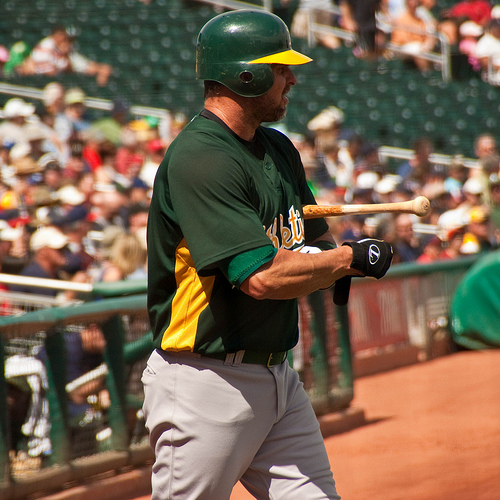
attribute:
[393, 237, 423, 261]
shirt — blue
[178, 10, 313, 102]
green/yellow helmet — green, yellow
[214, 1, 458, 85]
rail — long, gray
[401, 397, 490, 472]
dirt — clay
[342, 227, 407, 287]
glove — black, white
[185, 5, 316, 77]
helmet — green, yellow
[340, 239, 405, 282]
glove — black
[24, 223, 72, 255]
hat — white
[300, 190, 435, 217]
baseball bat — wooden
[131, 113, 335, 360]
shirt — yellow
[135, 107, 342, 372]
shirt — green, yellow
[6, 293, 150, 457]
padding — green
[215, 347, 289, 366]
belt — green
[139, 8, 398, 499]
man — dressed